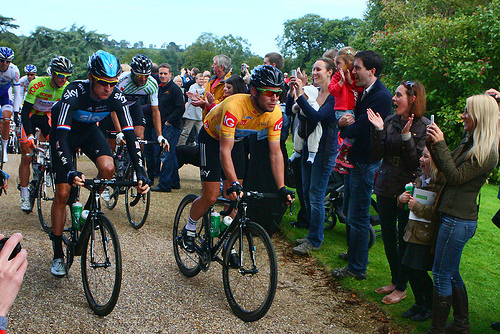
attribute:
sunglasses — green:
[249, 83, 288, 98]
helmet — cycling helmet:
[247, 64, 292, 94]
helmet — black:
[249, 63, 284, 89]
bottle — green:
[216, 204, 226, 239]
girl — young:
[309, 36, 382, 202]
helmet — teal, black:
[82, 46, 128, 86]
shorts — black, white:
[196, 132, 256, 185]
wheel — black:
[221, 221, 278, 324]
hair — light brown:
[403, 80, 427, 117]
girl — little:
[393, 140, 443, 330]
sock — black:
[48, 235, 68, 258]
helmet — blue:
[79, 48, 124, 78]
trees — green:
[284, 0, 496, 114]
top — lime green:
[20, 70, 72, 117]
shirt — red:
[322, 73, 354, 109]